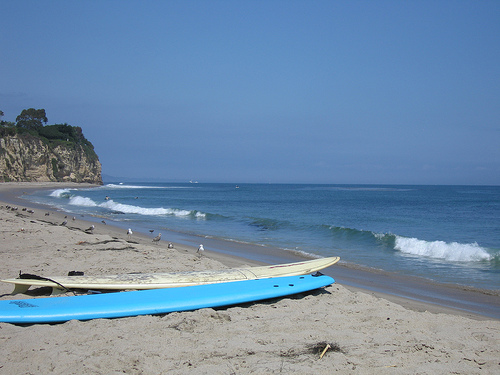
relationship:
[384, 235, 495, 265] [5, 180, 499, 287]
waves of ocean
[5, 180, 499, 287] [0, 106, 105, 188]
ocean near cliff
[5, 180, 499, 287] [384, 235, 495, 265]
ocean with waves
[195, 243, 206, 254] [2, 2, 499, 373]
seagull at a beach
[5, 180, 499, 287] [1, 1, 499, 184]
ocean meeting sky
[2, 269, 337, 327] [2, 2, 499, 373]
surfboard at a beach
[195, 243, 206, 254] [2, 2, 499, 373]
seagull standing at beach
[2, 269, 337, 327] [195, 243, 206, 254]
surfboard near seagull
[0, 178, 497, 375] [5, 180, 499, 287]
sand near ocean